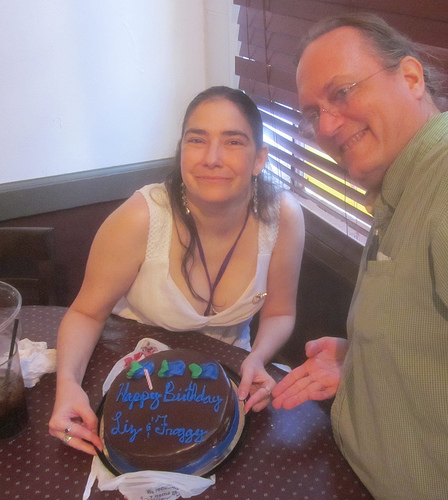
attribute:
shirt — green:
[331, 107, 447, 498]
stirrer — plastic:
[9, 317, 19, 372]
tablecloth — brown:
[3, 305, 391, 498]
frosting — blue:
[105, 379, 224, 450]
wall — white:
[3, 3, 265, 180]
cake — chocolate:
[87, 343, 255, 485]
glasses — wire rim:
[292, 63, 405, 140]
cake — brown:
[100, 344, 238, 474]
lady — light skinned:
[53, 53, 314, 415]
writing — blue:
[115, 380, 219, 442]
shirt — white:
[111, 194, 288, 333]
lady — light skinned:
[51, 84, 306, 457]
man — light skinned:
[265, 13, 446, 482]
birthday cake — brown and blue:
[101, 347, 241, 475]